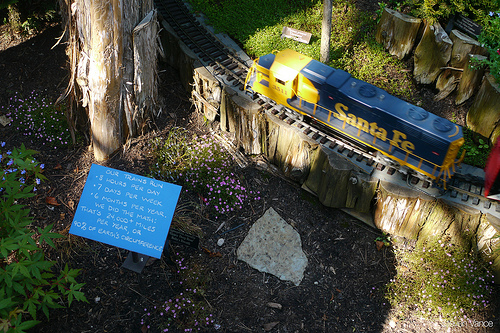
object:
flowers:
[138, 287, 215, 329]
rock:
[235, 200, 305, 286]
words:
[96, 218, 109, 226]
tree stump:
[50, 0, 169, 164]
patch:
[382, 225, 497, 323]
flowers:
[382, 232, 497, 304]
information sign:
[283, 28, 312, 45]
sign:
[71, 161, 183, 261]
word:
[106, 169, 120, 177]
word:
[124, 174, 147, 185]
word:
[149, 180, 163, 188]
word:
[104, 187, 121, 195]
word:
[141, 197, 162, 207]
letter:
[335, 102, 348, 120]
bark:
[377, 8, 422, 59]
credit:
[432, 320, 492, 329]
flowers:
[182, 140, 260, 217]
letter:
[329, 102, 418, 155]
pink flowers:
[1, 87, 76, 151]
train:
[244, 49, 463, 192]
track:
[162, 0, 498, 216]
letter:
[390, 130, 407, 149]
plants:
[4, 149, 96, 331]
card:
[453, 12, 482, 42]